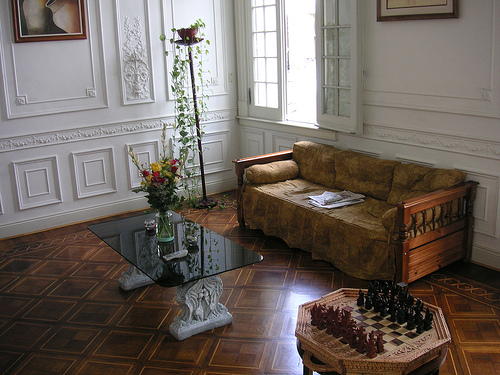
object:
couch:
[232, 140, 480, 284]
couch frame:
[231, 150, 479, 286]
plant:
[158, 14, 227, 216]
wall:
[0, 2, 240, 219]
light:
[273, 281, 325, 373]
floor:
[2, 189, 497, 375]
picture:
[16, 1, 84, 39]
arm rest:
[231, 149, 294, 175]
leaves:
[171, 82, 195, 150]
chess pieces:
[311, 302, 384, 357]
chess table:
[293, 280, 450, 374]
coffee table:
[84, 210, 264, 340]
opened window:
[281, 0, 319, 128]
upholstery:
[230, 141, 479, 291]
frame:
[7, 0, 90, 46]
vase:
[155, 211, 176, 243]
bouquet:
[123, 140, 187, 241]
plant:
[159, 15, 230, 210]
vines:
[160, 16, 212, 211]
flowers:
[124, 150, 182, 213]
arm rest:
[395, 179, 478, 241]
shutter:
[234, 0, 290, 123]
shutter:
[314, 0, 367, 137]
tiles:
[6, 254, 119, 374]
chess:
[295, 287, 452, 373]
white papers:
[306, 188, 371, 209]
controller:
[163, 250, 189, 261]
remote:
[164, 249, 190, 262]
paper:
[307, 190, 367, 210]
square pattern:
[232, 287, 282, 308]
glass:
[155, 212, 173, 242]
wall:
[338, 5, 498, 269]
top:
[85, 209, 264, 289]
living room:
[1, 0, 500, 375]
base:
[169, 275, 233, 341]